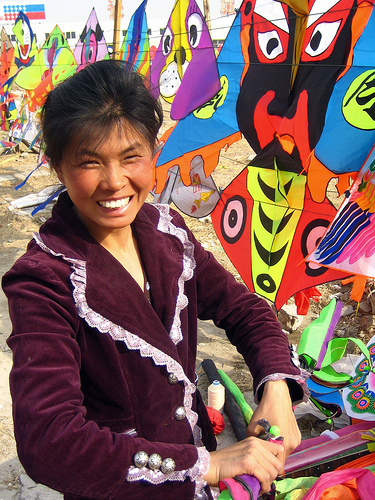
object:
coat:
[2, 192, 311, 499]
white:
[150, 201, 198, 343]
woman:
[0, 58, 302, 500]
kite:
[226, 421, 285, 499]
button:
[136, 450, 147, 466]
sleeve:
[9, 333, 211, 499]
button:
[149, 452, 161, 470]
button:
[163, 458, 175, 471]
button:
[177, 407, 185, 418]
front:
[3, 207, 217, 458]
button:
[170, 371, 180, 382]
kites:
[0, 0, 113, 166]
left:
[0, 0, 168, 499]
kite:
[149, 0, 223, 121]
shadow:
[3, 458, 67, 499]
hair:
[37, 58, 163, 173]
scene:
[0, 0, 374, 499]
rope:
[7, 4, 375, 51]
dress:
[0, 193, 305, 500]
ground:
[0, 128, 71, 499]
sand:
[2, 129, 64, 279]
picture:
[0, 3, 372, 498]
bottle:
[207, 381, 223, 436]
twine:
[207, 408, 226, 433]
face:
[160, 0, 203, 105]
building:
[4, 1, 368, 133]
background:
[1, 4, 372, 137]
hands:
[220, 398, 303, 491]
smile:
[94, 194, 134, 215]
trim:
[128, 446, 216, 497]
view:
[214, 3, 374, 313]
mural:
[215, 0, 374, 338]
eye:
[304, 20, 340, 56]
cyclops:
[11, 13, 40, 80]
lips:
[18, 44, 32, 57]